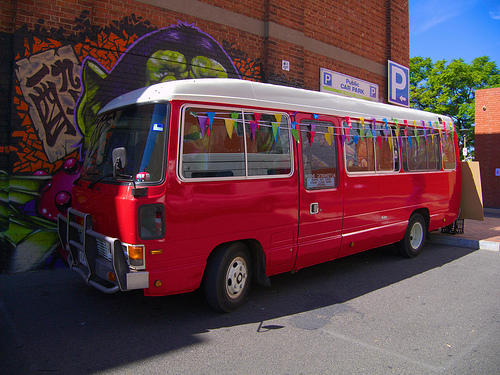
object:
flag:
[196, 114, 208, 139]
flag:
[205, 112, 217, 131]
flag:
[223, 118, 235, 139]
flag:
[248, 121, 259, 141]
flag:
[270, 121, 280, 140]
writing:
[23, 56, 93, 148]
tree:
[408, 53, 500, 162]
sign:
[389, 61, 411, 104]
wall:
[269, 14, 401, 54]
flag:
[327, 126, 336, 142]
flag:
[394, 128, 399, 142]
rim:
[226, 256, 249, 300]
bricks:
[215, 0, 407, 73]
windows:
[175, 108, 294, 179]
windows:
[343, 118, 456, 174]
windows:
[297, 115, 342, 193]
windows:
[75, 100, 170, 184]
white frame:
[173, 95, 468, 182]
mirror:
[109, 146, 129, 172]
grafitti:
[1, 8, 288, 273]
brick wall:
[0, 2, 411, 107]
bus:
[55, 77, 464, 314]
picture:
[0, 0, 500, 375]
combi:
[15, 3, 477, 313]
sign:
[320, 70, 382, 103]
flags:
[357, 116, 365, 130]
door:
[295, 113, 342, 267]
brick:
[38, 7, 83, 21]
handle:
[309, 200, 319, 215]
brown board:
[462, 158, 486, 222]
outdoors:
[0, 0, 500, 375]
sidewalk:
[432, 215, 499, 250]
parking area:
[4, 239, 496, 374]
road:
[1, 241, 498, 373]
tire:
[201, 238, 260, 314]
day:
[10, 9, 495, 374]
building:
[0, 0, 410, 278]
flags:
[344, 115, 353, 131]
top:
[94, 75, 458, 133]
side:
[117, 122, 187, 282]